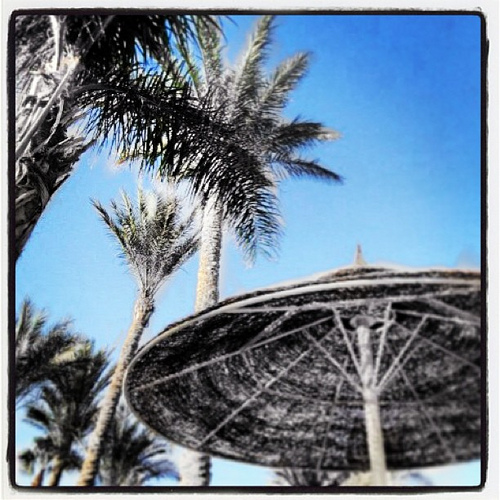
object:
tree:
[0, 0, 343, 309]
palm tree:
[14, 296, 76, 407]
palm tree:
[44, 342, 113, 488]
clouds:
[292, 187, 444, 257]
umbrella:
[119, 242, 482, 487]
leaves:
[72, 9, 345, 267]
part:
[421, 44, 458, 85]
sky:
[3, 12, 482, 359]